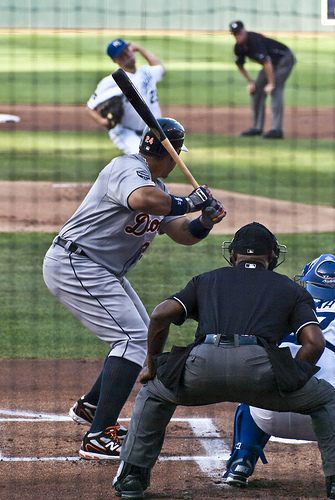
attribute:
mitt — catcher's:
[91, 95, 129, 128]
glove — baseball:
[99, 96, 124, 129]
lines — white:
[1, 405, 241, 485]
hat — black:
[227, 219, 277, 253]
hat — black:
[226, 18, 243, 34]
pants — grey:
[119, 331, 334, 476]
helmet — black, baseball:
[132, 114, 190, 164]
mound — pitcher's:
[225, 189, 293, 221]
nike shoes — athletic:
[49, 376, 145, 470]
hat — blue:
[106, 37, 127, 57]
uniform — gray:
[83, 165, 163, 353]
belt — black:
[117, 120, 170, 145]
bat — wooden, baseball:
[94, 70, 217, 210]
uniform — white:
[89, 65, 165, 145]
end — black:
[108, 68, 171, 140]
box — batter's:
[3, 381, 236, 469]